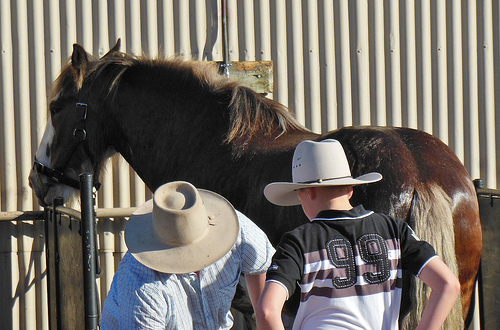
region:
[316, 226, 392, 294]
numbers at back of jersey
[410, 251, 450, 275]
white stripe on shirt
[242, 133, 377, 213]
cowboy hat on boy's head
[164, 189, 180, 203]
indent in man's hat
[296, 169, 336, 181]
black felt around hat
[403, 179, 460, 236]
tan tail on brown horse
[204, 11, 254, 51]
shiny black railing on wall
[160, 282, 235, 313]
blue stripe short sleeve shirt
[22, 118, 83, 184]
white face on horse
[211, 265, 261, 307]
pocket on blue shirt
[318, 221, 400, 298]
black stiched numbers on the boy's shirt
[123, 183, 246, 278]
a white leather cowboy hat on a man's head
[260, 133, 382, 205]
white leather coboyw hat with a black rope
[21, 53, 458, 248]
a brown horse in a pen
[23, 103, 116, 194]
black leather bridle on the horses head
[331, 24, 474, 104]
white metal wall of the building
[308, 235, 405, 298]
brown stripes on the boy's shirt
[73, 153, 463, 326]
two men standing next to a horse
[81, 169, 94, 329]
black metal post of the horse pen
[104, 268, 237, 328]
the man's pale blue button-up shirt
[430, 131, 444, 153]
part of a wall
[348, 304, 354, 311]
back of a boy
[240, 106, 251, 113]
part of a horse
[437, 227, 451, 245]
tail of a horse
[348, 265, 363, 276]
part of a cloth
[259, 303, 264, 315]
part of an elbow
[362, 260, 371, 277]
back of a boy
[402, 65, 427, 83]
part of a wall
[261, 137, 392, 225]
boy wearing a white hat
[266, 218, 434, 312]
boy wearing a black and white shirt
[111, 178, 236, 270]
man wearing a white hat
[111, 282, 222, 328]
Man wearing a plaid shirt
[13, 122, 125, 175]
Horse near a stable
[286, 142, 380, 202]
Boy in a cowboy hat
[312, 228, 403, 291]
number 99 on a shirt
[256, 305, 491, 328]
boy with hand on his hips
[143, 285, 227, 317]
blue and white plaid shirt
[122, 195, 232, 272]
Man wearing a tan hat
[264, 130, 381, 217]
The boy is wearing a cowboy hat.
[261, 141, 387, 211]
The cowboy hat is white.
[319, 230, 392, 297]
The number on the boys shirt is black.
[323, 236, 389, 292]
The number on the boys shirt is ninety-nine.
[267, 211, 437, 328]
The boys shirt is black, white and purple.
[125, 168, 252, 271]
The mans hat is white.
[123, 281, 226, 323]
The man's shirt is light in color.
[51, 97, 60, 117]
The horses eye is black.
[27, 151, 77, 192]
The horses bridle is brown.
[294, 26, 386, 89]
The wall in the background is biege.